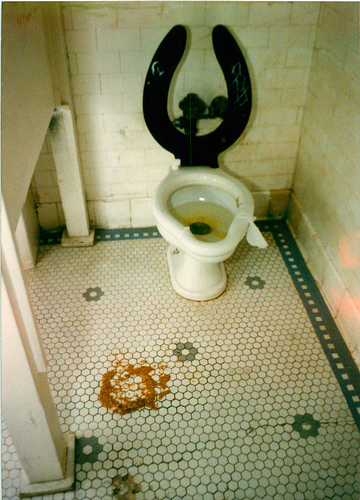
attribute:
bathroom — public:
[3, 1, 359, 499]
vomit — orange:
[87, 353, 215, 447]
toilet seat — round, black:
[144, 19, 258, 167]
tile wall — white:
[285, 1, 358, 326]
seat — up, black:
[148, 30, 245, 158]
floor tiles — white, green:
[2, 209, 356, 497]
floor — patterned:
[62, 298, 324, 499]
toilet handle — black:
[170, 115, 182, 129]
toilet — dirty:
[137, 25, 263, 303]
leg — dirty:
[48, 126, 87, 223]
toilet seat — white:
[141, 24, 253, 168]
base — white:
[277, 205, 359, 362]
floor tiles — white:
[159, 300, 330, 361]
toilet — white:
[143, 128, 258, 270]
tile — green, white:
[221, 309, 326, 422]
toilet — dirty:
[141, 145, 253, 251]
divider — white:
[1, 1, 96, 496]